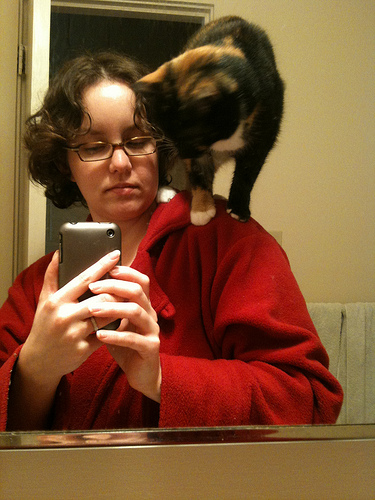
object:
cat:
[134, 14, 288, 227]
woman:
[0, 48, 345, 427]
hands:
[33, 249, 160, 395]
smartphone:
[57, 220, 122, 337]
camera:
[106, 229, 114, 238]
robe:
[0, 184, 343, 433]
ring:
[89, 316, 98, 331]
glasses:
[64, 135, 157, 163]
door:
[0, 0, 19, 309]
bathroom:
[0, 0, 375, 500]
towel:
[306, 302, 375, 426]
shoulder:
[153, 183, 279, 268]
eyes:
[85, 146, 105, 151]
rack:
[304, 300, 374, 313]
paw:
[190, 191, 216, 225]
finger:
[90, 316, 98, 331]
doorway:
[44, 4, 204, 256]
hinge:
[18, 46, 25, 75]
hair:
[23, 50, 179, 210]